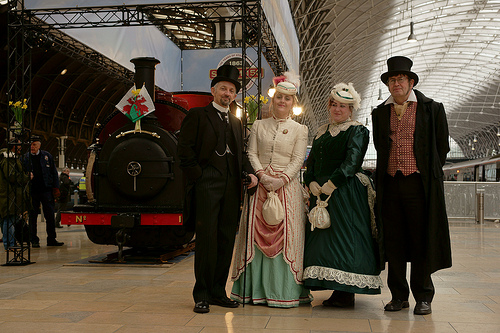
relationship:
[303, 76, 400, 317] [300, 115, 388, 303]
woman wearing dress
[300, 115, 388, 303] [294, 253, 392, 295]
dress with details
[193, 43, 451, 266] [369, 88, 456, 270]
man wearing wearing coat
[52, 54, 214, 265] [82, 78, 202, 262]
train has engine car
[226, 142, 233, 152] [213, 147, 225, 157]
watch has chain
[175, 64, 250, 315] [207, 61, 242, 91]
man wearing top hat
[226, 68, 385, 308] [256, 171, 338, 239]
women carrying purses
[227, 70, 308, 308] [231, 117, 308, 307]
girl in white dress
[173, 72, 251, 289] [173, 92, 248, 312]
man in suit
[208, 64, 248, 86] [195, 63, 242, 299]
hat on man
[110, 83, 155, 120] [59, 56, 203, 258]
decoration on train car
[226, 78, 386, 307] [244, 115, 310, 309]
women wearing dress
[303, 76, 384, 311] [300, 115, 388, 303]
woman wearing dress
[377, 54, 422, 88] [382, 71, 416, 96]
top hat on head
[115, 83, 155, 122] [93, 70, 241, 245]
decoration on train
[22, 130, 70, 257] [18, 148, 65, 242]
man wearing suit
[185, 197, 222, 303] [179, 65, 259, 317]
leg on man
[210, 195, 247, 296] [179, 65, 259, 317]
leg on man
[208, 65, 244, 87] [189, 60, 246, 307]
top hat on man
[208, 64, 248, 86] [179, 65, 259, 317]
hat on man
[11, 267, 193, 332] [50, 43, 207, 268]
ground in front of train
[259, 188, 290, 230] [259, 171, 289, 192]
purse in hand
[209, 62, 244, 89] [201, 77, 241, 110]
hat on head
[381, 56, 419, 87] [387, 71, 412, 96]
hat on head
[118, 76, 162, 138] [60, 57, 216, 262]
flag on engine car